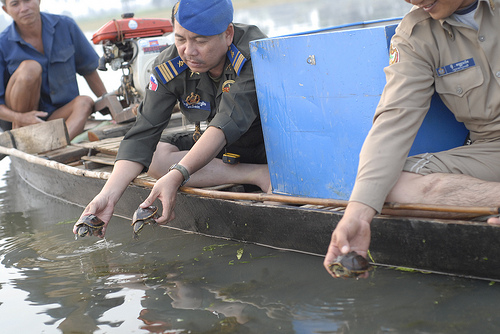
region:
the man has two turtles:
[55, 205, 177, 247]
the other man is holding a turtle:
[325, 232, 389, 292]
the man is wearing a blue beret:
[170, 2, 244, 39]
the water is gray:
[11, 241, 281, 322]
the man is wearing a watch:
[155, 162, 212, 194]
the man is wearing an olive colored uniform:
[106, 40, 271, 192]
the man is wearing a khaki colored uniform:
[350, 13, 498, 225]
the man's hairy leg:
[400, 172, 498, 217]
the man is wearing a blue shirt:
[2, 17, 121, 109]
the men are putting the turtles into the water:
[75, 137, 395, 307]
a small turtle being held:
[324, 249, 382, 285]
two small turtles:
[63, 187, 176, 254]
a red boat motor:
[98, 12, 171, 101]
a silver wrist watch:
[159, 136, 209, 222]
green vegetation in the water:
[100, 243, 286, 288]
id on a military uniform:
[431, 50, 481, 86]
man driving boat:
[0, 0, 131, 145]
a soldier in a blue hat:
[126, 0, 269, 195]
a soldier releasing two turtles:
[67, 0, 293, 291]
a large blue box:
[258, 13, 423, 224]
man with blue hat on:
[65, 6, 257, 246]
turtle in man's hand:
[298, 204, 389, 313]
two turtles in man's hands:
[32, 161, 194, 273]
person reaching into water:
[37, 132, 210, 267]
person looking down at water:
[49, 4, 257, 235]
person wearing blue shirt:
[7, 1, 102, 72]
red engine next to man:
[102, 2, 161, 69]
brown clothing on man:
[327, 113, 459, 222]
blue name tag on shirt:
[424, 52, 481, 96]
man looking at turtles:
[115, 3, 252, 153]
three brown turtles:
[62, 206, 384, 288]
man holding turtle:
[120, 3, 269, 270]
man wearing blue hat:
[135, 8, 302, 123]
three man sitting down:
[7, 11, 497, 213]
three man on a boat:
[35, 0, 420, 294]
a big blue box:
[232, 24, 459, 196]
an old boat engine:
[95, 23, 227, 134]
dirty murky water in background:
[27, 191, 372, 332]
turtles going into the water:
[27, 180, 262, 297]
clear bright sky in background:
[50, 3, 372, 88]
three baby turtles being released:
[43, 181, 375, 300]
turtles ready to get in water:
[62, 199, 180, 263]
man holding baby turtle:
[319, 231, 391, 293]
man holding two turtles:
[91, 9, 233, 301]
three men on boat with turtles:
[12, 3, 494, 292]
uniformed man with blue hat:
[133, 4, 272, 94]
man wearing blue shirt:
[2, 1, 104, 161]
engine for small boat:
[75, 8, 183, 108]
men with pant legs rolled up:
[93, 119, 490, 280]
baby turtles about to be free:
[44, 184, 414, 309]